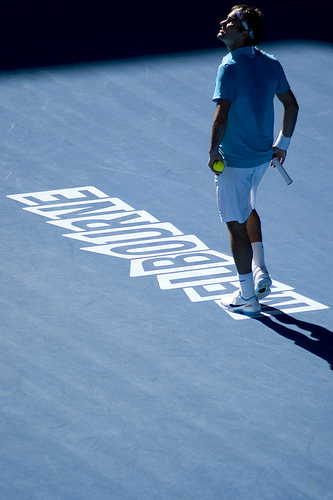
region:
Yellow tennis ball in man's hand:
[208, 152, 225, 174]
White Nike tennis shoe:
[220, 290, 261, 315]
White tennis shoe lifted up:
[253, 266, 272, 301]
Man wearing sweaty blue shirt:
[222, 53, 281, 161]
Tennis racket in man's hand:
[270, 147, 292, 186]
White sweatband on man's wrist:
[274, 129, 291, 153]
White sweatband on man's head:
[215, 3, 263, 48]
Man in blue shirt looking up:
[216, 4, 287, 165]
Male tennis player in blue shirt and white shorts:
[208, 2, 301, 226]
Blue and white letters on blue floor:
[13, 183, 328, 321]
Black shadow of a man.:
[245, 297, 332, 368]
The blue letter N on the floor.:
[36, 200, 124, 219]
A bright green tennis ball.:
[212, 158, 224, 172]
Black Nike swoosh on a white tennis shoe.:
[229, 299, 246, 308]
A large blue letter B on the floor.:
[141, 252, 229, 271]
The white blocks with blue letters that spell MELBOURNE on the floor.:
[7, 186, 329, 319]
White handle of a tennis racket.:
[271, 158, 292, 186]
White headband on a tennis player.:
[234, 5, 254, 37]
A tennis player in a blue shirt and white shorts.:
[208, 4, 300, 317]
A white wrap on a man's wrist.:
[274, 129, 291, 150]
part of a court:
[302, 378, 306, 384]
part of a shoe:
[253, 305, 258, 311]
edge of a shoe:
[240, 306, 245, 319]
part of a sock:
[249, 278, 252, 280]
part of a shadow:
[272, 313, 277, 341]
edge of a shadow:
[293, 355, 295, 364]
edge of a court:
[189, 392, 194, 401]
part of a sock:
[245, 290, 247, 295]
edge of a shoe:
[266, 338, 272, 355]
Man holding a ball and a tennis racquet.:
[206, 2, 296, 313]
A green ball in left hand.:
[204, 148, 220, 172]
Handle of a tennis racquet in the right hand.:
[266, 142, 286, 179]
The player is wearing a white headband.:
[230, 5, 254, 37]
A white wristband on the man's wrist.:
[270, 129, 286, 143]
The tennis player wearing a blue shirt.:
[208, 44, 281, 159]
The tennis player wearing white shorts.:
[211, 163, 261, 221]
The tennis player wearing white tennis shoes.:
[218, 267, 270, 310]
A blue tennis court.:
[0, 40, 330, 495]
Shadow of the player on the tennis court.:
[247, 303, 330, 365]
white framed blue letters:
[5, 176, 329, 341]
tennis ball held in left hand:
[206, 148, 229, 178]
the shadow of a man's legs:
[250, 299, 331, 369]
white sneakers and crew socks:
[219, 238, 276, 315]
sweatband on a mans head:
[228, 2, 264, 39]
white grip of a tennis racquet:
[270, 144, 293, 191]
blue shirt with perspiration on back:
[211, 41, 288, 165]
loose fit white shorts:
[210, 171, 265, 223]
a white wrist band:
[275, 122, 292, 155]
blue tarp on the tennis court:
[1, 48, 332, 498]